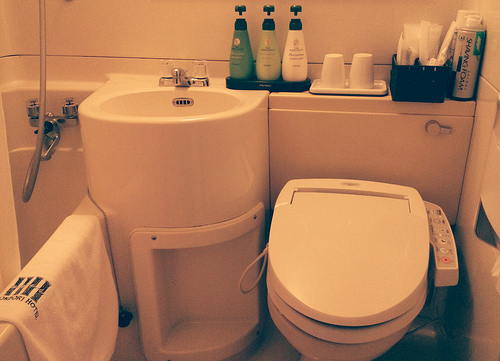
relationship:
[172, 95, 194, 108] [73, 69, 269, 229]
drain in sink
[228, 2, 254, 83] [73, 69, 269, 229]
bottle sitting to right of sink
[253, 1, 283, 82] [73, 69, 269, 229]
bottle sitting to right of sink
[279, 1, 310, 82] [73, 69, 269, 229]
bottle sitting to right of sink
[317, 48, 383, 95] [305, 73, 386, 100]
cups on tray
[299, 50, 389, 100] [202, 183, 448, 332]
two stacks tacks of cups on back of a toilet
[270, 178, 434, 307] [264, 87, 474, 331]
lid on toilet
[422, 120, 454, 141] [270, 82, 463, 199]
knob on tank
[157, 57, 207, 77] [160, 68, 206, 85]
knobs on faucet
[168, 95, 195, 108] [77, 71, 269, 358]
drain on bathroom sink